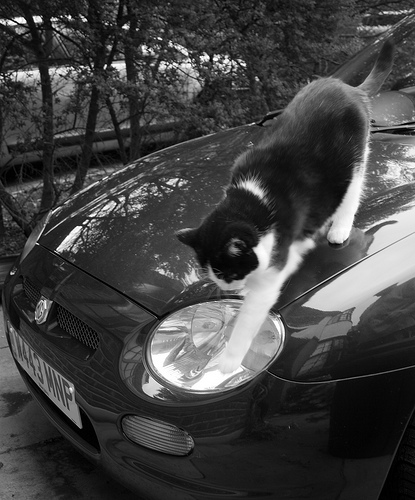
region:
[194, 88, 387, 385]
black and white cat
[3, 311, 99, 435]
license plate on front of car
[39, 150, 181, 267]
reflection of tree branches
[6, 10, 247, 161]
white car parked behind trees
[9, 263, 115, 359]
front grill of car with logo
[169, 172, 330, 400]
cat with front paw stretched out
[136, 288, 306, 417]
headlight of a car with cats paw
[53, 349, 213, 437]
reflection of bricks on car bumper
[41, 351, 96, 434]
the letters of MNP on license plate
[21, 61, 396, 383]
car hood with a cat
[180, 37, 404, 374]
the cat is on the car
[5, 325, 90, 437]
the car has a plate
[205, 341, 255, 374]
the cat has a paw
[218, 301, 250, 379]
the paw is on the headlight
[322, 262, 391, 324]
the car is shiney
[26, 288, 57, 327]
the car has an emblem infront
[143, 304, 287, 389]
the headlight is off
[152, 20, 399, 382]
the cat is black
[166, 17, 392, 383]
the cat is white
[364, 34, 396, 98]
the cat has a tail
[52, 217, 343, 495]
the car is shiny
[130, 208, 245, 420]
the car is shiny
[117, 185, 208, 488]
the car is shiny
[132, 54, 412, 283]
the cat is black and white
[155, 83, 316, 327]
the cat is black and white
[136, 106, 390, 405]
the cat is black and white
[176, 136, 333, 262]
the cat is black and white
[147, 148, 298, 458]
a cat on car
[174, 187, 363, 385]
a cat on car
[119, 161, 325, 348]
a cat on car